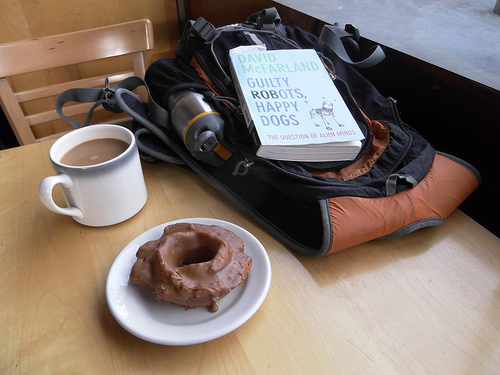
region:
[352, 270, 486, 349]
the table is wooden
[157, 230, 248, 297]
the cake is choclate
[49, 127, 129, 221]
the caup has tea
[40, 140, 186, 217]
the caup is grey and white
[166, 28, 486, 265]
the bag is orange and black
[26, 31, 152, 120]
the chair is wooden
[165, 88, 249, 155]
the plastic is white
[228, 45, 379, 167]
the book tiitle is guilty diogs happy dogs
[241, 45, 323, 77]
the author is david mcfarland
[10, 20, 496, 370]
the scene is indoors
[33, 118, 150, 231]
white and grey mug containing a hot drink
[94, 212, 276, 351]
chocolate donut on a round white plate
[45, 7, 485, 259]
backpack on a table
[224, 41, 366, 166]
paperback book on a backback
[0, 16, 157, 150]
wooden ladder back dining chair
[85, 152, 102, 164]
bubbles in the center of a hot drink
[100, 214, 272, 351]
circular white plate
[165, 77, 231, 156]
water bottle strapped to a backpack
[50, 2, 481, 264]
brown and black backpack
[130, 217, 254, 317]
donut with chocolate frosting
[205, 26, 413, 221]
a book on a backpack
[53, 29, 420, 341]
the meal is breakfast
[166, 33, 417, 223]
a waterbottle, book, and backpack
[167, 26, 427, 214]
the backpack is orange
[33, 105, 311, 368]
coffee and a donut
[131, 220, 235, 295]
the donut has chocolate frosting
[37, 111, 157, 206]
the coffee has milk in it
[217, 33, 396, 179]
the book is by david mcfarland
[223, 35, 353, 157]
the book is called guilty robots, happy dogs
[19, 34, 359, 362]
a breakfast for traveling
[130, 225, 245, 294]
this is a doughnut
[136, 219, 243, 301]
the doughnut is brown in color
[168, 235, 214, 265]
the doughnut has hole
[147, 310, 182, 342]
this is a sauce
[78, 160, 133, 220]
this is a cup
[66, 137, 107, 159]
the cup has tea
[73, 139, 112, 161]
the tea is brown in color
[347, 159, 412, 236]
this is a bag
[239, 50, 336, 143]
a book is on the bag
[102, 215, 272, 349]
Donut sitting on a white plate.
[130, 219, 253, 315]
Glazed donut.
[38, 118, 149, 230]
Mug of coffee.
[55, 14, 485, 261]
Black backpack with brown interior.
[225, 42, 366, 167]
Paperback book.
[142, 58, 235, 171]
Metallic water bottle.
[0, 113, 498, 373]
Brown wooden table.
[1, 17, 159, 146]
Brown wooden chair.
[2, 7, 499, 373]
Table with a backpack, coffee and donut on it.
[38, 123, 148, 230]
White mug rimmed with grey.